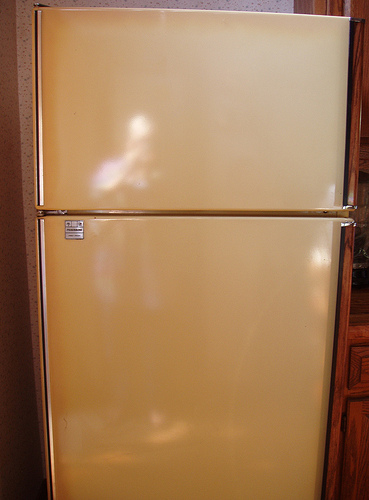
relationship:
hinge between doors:
[30, 206, 74, 219] [23, 8, 351, 209]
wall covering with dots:
[11, 16, 42, 296] [15, 33, 27, 68]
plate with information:
[53, 212, 96, 250] [65, 228, 82, 230]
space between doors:
[29, 196, 359, 236] [29, 226, 324, 489]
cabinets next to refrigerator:
[313, 21, 363, 487] [34, 15, 344, 492]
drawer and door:
[339, 338, 363, 392] [340, 391, 362, 486]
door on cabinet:
[340, 391, 362, 486] [342, 268, 364, 489]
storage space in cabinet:
[343, 101, 364, 327] [346, 14, 366, 171]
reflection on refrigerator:
[65, 102, 202, 479] [33, 13, 357, 498]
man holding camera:
[59, 93, 182, 239] [122, 137, 158, 177]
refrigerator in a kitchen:
[6, 29, 360, 493] [21, 32, 358, 480]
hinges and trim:
[344, 193, 358, 216] [338, 10, 368, 212]